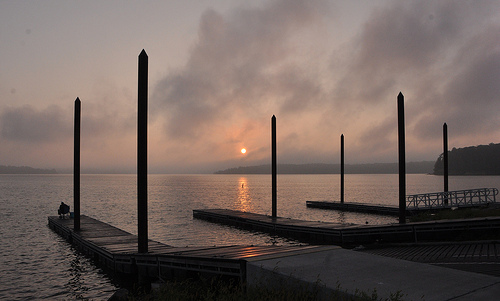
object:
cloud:
[0, 97, 122, 144]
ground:
[425, 97, 499, 150]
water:
[3, 172, 497, 299]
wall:
[239, 106, 256, 141]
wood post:
[72, 97, 81, 229]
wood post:
[271, 116, 277, 222]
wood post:
[397, 93, 406, 223]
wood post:
[339, 134, 344, 202]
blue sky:
[0, 0, 494, 171]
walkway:
[351, 244, 500, 276]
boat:
[192, 208, 354, 246]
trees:
[444, 144, 497, 180]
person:
[58, 201, 71, 219]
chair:
[58, 206, 72, 220]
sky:
[0, 0, 500, 175]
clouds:
[350, 111, 411, 153]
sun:
[240, 148, 247, 154]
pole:
[134, 48, 150, 250]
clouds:
[272, 82, 330, 122]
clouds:
[459, 58, 488, 103]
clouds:
[329, 1, 476, 117]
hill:
[427, 142, 500, 176]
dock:
[48, 209, 498, 299]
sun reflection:
[235, 177, 252, 210]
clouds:
[410, 27, 500, 150]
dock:
[307, 198, 500, 222]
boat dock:
[191, 206, 500, 245]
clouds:
[152, 0, 332, 147]